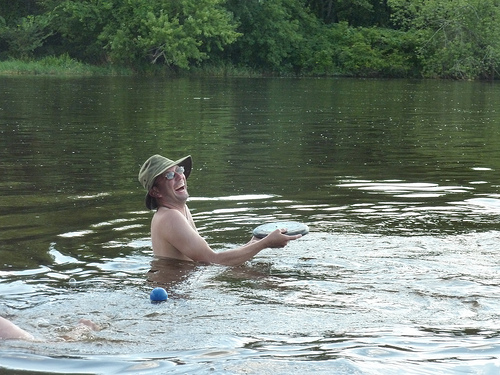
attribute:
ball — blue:
[136, 280, 173, 310]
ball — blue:
[119, 289, 191, 321]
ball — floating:
[147, 285, 168, 303]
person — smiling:
[129, 146, 348, 319]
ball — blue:
[150, 285, 168, 305]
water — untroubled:
[231, 92, 408, 205]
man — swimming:
[97, 133, 233, 295]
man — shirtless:
[123, 131, 326, 290]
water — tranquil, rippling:
[5, 77, 500, 371]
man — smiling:
[94, 144, 359, 319]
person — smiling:
[132, 147, 302, 279]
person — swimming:
[88, 151, 308, 273]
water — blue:
[27, 87, 485, 352]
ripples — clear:
[366, 186, 473, 298]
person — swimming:
[84, 159, 289, 294]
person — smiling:
[123, 144, 220, 231]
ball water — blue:
[120, 284, 204, 313]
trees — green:
[21, 17, 72, 62]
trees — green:
[87, 15, 148, 60]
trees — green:
[151, 5, 246, 72]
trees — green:
[256, 10, 346, 68]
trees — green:
[350, 13, 475, 73]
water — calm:
[9, 79, 467, 346]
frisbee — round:
[249, 218, 312, 243]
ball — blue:
[125, 274, 195, 328]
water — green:
[197, 78, 498, 172]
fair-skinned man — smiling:
[0, 149, 295, 352]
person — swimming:
[68, 137, 328, 319]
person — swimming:
[134, 150, 302, 268]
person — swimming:
[137, 153, 298, 290]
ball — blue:
[143, 284, 172, 305]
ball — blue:
[149, 285, 169, 301]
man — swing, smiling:
[131, 150, 302, 267]